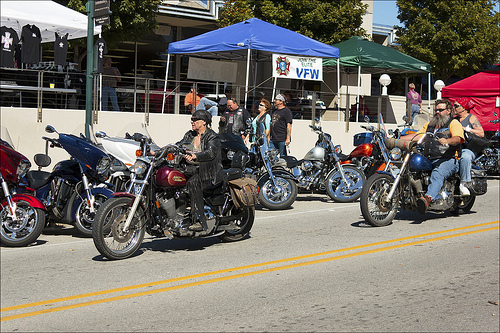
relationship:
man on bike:
[452, 95, 484, 195] [359, 119, 488, 229]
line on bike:
[0, 222, 497, 324] [80, 127, 260, 261]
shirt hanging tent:
[54, 32, 69, 66] [0, 0, 96, 63]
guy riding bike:
[173, 110, 222, 231] [349, 132, 497, 231]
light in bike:
[123, 149, 153, 179] [97, 150, 263, 264]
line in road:
[0, 222, 497, 324] [0, 171, 497, 331]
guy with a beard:
[413, 100, 466, 213] [429, 113, 454, 128]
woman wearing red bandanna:
[453, 95, 486, 202] [457, 97, 475, 111]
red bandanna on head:
[457, 97, 475, 111] [453, 97, 470, 115]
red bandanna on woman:
[457, 97, 475, 111] [453, 95, 486, 202]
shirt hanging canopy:
[51, 33, 67, 63] [0, 0, 102, 45]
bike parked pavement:
[93, 125, 257, 264] [0, 185, 497, 332]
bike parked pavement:
[24, 118, 118, 235] [0, 185, 497, 332]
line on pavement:
[0, 222, 497, 324] [240, 277, 315, 324]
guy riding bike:
[128, 80, 257, 242] [67, 95, 347, 281]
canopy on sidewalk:
[158, 16, 344, 115] [0, 102, 411, 172]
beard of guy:
[427, 111, 452, 128] [394, 97, 467, 211]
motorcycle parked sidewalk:
[279, 141, 351, 196] [295, 196, 350, 238]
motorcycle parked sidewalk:
[81, 130, 164, 177] [295, 196, 350, 238]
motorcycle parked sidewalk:
[248, 152, 298, 204] [295, 196, 350, 238]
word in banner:
[299, 60, 314, 69] [268, 51, 323, 81]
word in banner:
[298, 57, 317, 67] [268, 51, 323, 81]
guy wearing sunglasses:
[413, 100, 466, 213] [188, 116, 204, 123]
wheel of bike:
[93, 195, 146, 265] [93, 131, 257, 261]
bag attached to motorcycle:
[226, 172, 263, 209] [89, 129, 259, 262]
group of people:
[94, 55, 485, 246] [97, 95, 481, 254]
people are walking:
[210, 86, 287, 154] [219, 94, 294, 169]